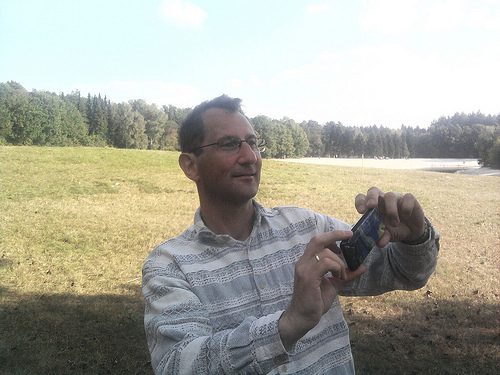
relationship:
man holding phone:
[136, 90, 442, 374] [340, 205, 388, 274]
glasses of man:
[214, 134, 270, 157] [136, 90, 442, 374]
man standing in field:
[136, 90, 442, 374] [280, 165, 346, 207]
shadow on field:
[0, 280, 500, 375] [0, 146, 93, 249]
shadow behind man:
[0, 280, 500, 375] [136, 90, 442, 374]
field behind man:
[0, 146, 93, 249] [136, 90, 442, 374]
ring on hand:
[312, 251, 321, 263] [286, 228, 366, 333]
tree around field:
[113, 106, 151, 149] [2, 138, 499, 374]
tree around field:
[0, 88, 49, 144] [2, 138, 499, 374]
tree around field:
[53, 103, 93, 145] [2, 138, 499, 374]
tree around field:
[85, 95, 111, 146] [2, 138, 499, 374]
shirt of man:
[137, 201, 441, 373] [136, 90, 442, 374]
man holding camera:
[136, 90, 442, 374] [341, 205, 388, 269]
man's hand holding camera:
[381, 195, 433, 253] [343, 222, 385, 281]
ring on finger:
[313, 252, 321, 263] [307, 244, 342, 261]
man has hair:
[136, 90, 442, 374] [180, 93, 245, 155]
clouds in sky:
[129, 5, 499, 107] [1, 1, 163, 73]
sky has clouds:
[1, 1, 163, 73] [129, 5, 499, 107]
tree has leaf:
[284, 117, 308, 156] [301, 135, 306, 137]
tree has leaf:
[139, 103, 167, 148] [146, 115, 154, 125]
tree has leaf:
[85, 92, 111, 146] [91, 105, 100, 115]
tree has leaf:
[0, 88, 49, 144] [118, 108, 137, 114]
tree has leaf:
[113, 106, 151, 149] [16, 96, 22, 108]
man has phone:
[136, 90, 442, 374] [340, 211, 382, 268]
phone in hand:
[340, 211, 382, 268] [277, 229, 369, 352]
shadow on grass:
[4, 290, 489, 369] [15, 314, 113, 360]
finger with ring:
[299, 228, 346, 287] [309, 250, 329, 268]